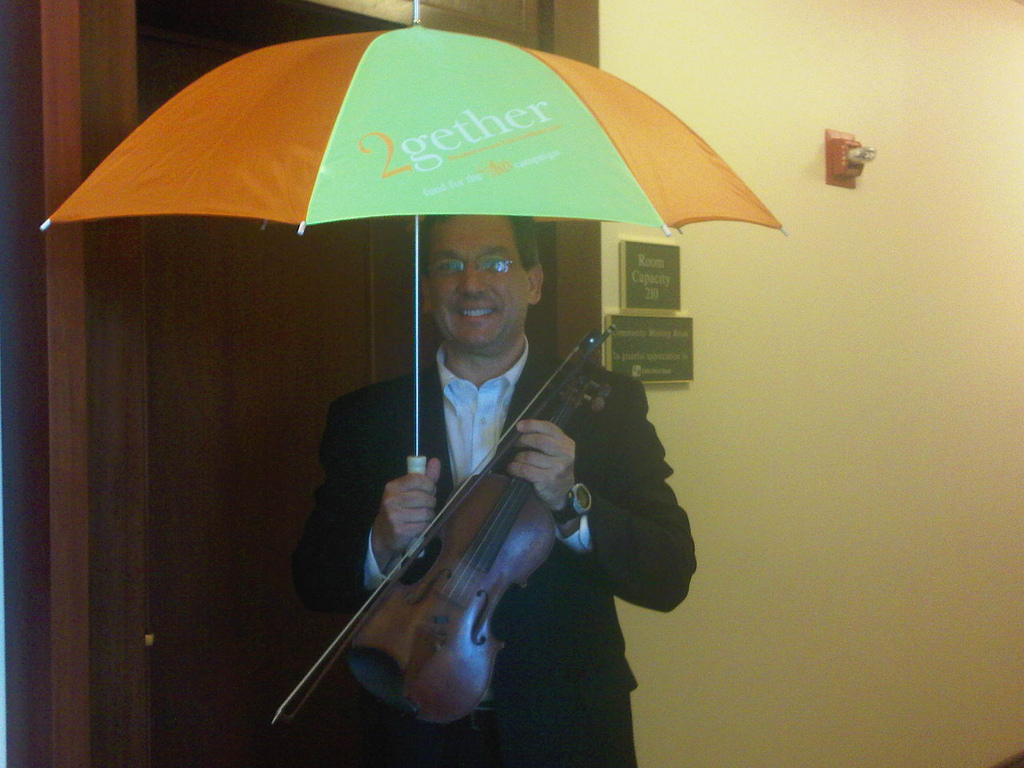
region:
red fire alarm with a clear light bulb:
[824, 132, 876, 190]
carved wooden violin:
[344, 363, 607, 728]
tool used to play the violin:
[266, 309, 618, 734]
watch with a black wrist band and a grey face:
[547, 480, 593, 525]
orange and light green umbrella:
[43, 0, 784, 561]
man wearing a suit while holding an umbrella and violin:
[287, 212, 699, 764]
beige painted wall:
[601, 0, 1022, 767]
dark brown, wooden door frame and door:
[0, 0, 604, 765]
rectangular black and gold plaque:
[601, 313, 697, 389]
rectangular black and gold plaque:
[615, 237, 688, 314]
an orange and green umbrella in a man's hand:
[53, 30, 799, 240]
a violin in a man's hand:
[346, 365, 606, 724]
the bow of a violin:
[270, 318, 594, 729]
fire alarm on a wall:
[823, 128, 874, 192]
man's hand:
[511, 412, 575, 510]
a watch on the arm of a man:
[555, 482, 591, 527]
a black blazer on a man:
[292, 356, 698, 764]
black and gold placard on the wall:
[605, 314, 700, 391]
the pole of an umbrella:
[413, 219, 427, 457]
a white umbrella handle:
[404, 456, 428, 559]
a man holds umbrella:
[24, 7, 806, 258]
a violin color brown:
[240, 297, 637, 753]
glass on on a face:
[420, 244, 523, 286]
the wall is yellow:
[612, 4, 1021, 766]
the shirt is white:
[428, 334, 542, 487]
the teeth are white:
[451, 293, 503, 326]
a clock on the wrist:
[548, 476, 602, 537]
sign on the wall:
[604, 306, 702, 393]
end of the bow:
[558, 312, 613, 348]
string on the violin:
[384, 568, 438, 594]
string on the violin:
[469, 554, 485, 567]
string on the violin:
[475, 524, 489, 531]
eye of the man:
[422, 246, 462, 285]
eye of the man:
[463, 239, 493, 282]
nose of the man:
[441, 275, 498, 304]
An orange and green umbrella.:
[30, 28, 793, 241]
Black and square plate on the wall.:
[617, 237, 684, 311]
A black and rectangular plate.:
[605, 316, 698, 387]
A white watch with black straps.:
[552, 481, 595, 527]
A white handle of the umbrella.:
[405, 452, 428, 481]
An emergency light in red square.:
[820, 127, 881, 191]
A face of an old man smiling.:
[421, 218, 549, 352]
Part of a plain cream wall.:
[724, 246, 1022, 746]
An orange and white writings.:
[358, 95, 565, 190]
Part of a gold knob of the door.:
[141, 630, 158, 651]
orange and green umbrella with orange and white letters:
[40, 21, 790, 236]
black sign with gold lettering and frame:
[613, 232, 687, 313]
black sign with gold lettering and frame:
[603, 303, 699, 390]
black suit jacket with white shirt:
[282, 338, 698, 766]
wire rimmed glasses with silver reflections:
[429, 246, 534, 281]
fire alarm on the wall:
[807, 116, 910, 205]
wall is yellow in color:
[647, 25, 1005, 756]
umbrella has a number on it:
[344, 95, 421, 181]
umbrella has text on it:
[393, 98, 562, 175]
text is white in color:
[410, 81, 559, 165]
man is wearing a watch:
[539, 464, 600, 538]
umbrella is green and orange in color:
[36, 16, 767, 252]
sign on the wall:
[600, 297, 719, 387]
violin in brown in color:
[337, 397, 576, 742]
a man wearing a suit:
[263, 139, 777, 734]